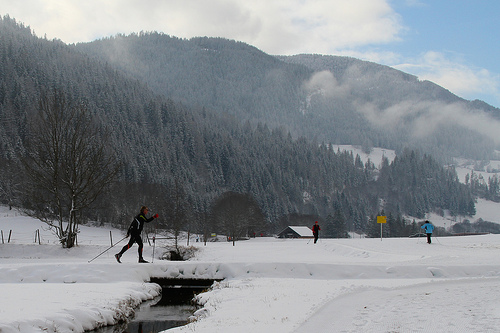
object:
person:
[114, 206, 159, 264]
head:
[140, 205, 148, 215]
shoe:
[138, 257, 151, 264]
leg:
[136, 234, 149, 264]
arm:
[144, 216, 154, 224]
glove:
[153, 213, 159, 218]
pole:
[86, 235, 130, 264]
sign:
[376, 215, 387, 223]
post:
[381, 223, 383, 241]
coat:
[421, 223, 434, 234]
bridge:
[152, 260, 237, 282]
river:
[136, 242, 210, 325]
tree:
[16, 81, 115, 248]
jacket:
[125, 213, 152, 234]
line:
[311, 298, 333, 322]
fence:
[0, 228, 54, 246]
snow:
[391, 264, 426, 283]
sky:
[422, 16, 481, 79]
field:
[129, 216, 491, 324]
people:
[420, 219, 434, 244]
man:
[312, 220, 322, 243]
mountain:
[87, 18, 204, 71]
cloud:
[249, 4, 291, 31]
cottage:
[278, 225, 318, 238]